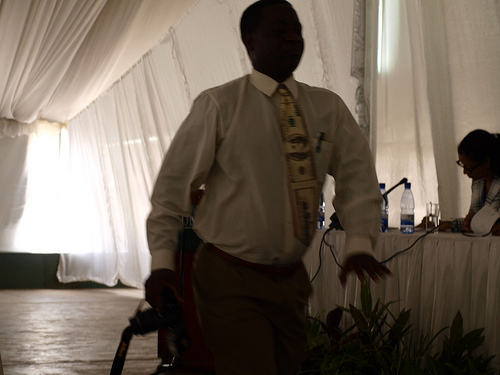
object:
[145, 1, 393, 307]
man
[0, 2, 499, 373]
wedding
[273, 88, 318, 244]
tie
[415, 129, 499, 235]
woman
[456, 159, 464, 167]
glasses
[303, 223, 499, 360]
table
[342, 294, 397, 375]
plant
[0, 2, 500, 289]
tent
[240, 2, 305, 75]
head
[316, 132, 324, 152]
stuff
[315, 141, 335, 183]
pocket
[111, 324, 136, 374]
cane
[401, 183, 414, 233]
bottle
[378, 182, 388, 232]
bottle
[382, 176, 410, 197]
microphone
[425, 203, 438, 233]
glass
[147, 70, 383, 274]
shirt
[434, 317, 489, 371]
planter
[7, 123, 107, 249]
sunlight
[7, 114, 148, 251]
window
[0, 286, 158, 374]
floor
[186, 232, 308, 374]
pants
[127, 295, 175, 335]
camera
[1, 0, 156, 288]
curtain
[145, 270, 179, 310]
hand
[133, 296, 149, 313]
strap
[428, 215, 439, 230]
water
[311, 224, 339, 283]
cable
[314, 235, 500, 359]
cloth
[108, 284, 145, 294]
light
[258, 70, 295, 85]
neck